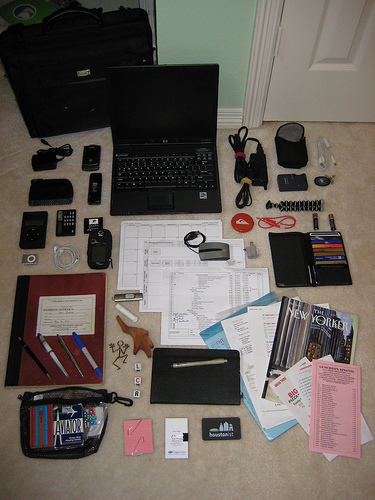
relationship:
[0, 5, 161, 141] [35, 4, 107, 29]
bag with handle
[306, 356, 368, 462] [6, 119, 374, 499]
page on floor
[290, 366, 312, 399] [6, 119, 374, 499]
page on floor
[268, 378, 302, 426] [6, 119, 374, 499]
page on floor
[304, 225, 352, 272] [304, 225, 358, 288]
credit cards in slots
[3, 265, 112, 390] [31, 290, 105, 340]
notebook has label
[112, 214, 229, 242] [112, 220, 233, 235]
block on blocks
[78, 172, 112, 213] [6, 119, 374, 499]
battery on floor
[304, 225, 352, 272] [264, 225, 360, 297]
credit cards in wallet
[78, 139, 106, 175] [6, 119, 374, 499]
battery on carpet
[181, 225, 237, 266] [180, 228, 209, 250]
mouse with cord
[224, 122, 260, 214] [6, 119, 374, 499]
cord on carpet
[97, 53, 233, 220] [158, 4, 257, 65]
laptop near wall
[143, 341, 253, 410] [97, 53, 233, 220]
case of laptop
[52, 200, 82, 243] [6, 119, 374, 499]
calculator on carpet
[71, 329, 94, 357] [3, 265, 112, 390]
pen on notebook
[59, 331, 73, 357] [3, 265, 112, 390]
pen on notebook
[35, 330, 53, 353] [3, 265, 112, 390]
pen on notebook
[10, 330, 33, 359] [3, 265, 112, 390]
pen on notebook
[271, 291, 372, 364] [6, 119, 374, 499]
pamphlet on carpet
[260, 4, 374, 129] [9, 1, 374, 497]
door in room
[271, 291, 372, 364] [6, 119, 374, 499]
magazine on carpet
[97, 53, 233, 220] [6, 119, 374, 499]
laptop on floor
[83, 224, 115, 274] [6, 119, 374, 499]
ipod on floor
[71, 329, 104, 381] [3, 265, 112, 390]
pen on notebook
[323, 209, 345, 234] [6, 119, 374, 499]
usb on carpet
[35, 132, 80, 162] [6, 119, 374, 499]
cable on floor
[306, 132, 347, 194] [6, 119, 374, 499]
earphones on floor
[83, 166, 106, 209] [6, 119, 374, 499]
remote control on floor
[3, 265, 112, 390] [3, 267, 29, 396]
notebook with black binder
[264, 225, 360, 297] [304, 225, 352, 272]
wallet with credit cards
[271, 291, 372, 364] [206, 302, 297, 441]
magazine under pamplets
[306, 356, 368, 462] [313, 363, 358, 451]
pamphlet with black words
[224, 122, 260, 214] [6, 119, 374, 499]
cord on floor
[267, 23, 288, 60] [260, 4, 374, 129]
hinge of door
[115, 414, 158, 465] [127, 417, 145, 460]
card with clips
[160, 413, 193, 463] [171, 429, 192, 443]
card with clip